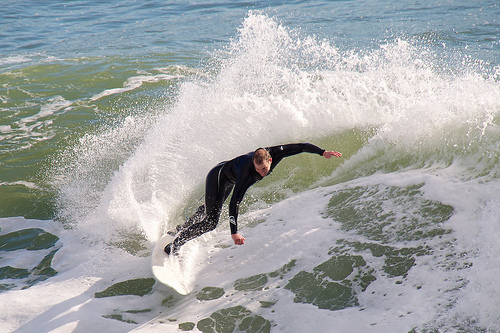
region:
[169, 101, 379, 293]
A man surfing in the ocean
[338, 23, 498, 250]
Waves in the ocean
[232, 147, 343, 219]
A man in a black wet suit.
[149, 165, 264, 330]
A man riding a surfboard.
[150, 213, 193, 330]
A white surfboard in the ocean.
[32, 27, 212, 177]
Waves and ocean water.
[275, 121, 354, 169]
A man's arm and hand.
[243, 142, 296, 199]
A man in the ocean.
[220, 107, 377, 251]
A man with out stretched arms.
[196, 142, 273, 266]
A black wet suit.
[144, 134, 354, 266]
Man surfing on a wave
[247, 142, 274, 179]
Man's head pointed towards the ground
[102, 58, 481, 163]
White foamy crest of the wave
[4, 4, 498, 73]
Ocean in the background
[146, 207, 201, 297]
Man's feet on white surfboard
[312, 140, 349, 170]
Man's hand in the air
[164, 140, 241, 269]
Black tight wetsuit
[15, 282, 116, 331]
Patch of white sea foam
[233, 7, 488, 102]
Spray of ocean water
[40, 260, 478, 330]
Bottom of the wave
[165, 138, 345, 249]
man in black wetsuit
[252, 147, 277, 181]
surfer with bald spot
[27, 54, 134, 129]
murky ocean water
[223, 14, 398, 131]
sea spray made by rough surf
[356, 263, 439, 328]
foam at base of waves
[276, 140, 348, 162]
surfer's left arm extended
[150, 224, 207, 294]
white surfboard in water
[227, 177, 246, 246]
surfer's right arm extended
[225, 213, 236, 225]
writing on wetsuit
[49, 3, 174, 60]
calm water behind waves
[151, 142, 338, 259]
a surfer falling forward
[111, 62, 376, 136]
white spray behind the surfer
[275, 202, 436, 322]
green and white ocean water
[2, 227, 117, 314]
ocean water with foam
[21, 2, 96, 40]
calm blue ocean water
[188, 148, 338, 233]
a surfer wearing a black wetsuit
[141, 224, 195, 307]
a white surf board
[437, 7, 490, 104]
sunlight hitting the water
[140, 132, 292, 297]
a man on a surfboard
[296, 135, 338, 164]
a surfer's extended left arm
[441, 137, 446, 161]
part of the ocean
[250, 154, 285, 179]
head of a man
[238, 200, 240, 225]
arm of a man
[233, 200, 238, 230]
right arm of a man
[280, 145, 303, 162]
left arm of a man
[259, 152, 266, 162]
head of a man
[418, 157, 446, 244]
ripples of a wave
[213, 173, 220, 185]
back of a man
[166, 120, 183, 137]
part of the ocean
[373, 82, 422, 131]
section of a water wave